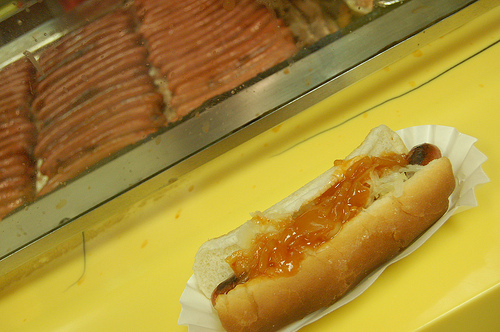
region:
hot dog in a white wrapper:
[181, 114, 483, 329]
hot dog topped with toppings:
[168, 122, 484, 329]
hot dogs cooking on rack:
[0, 4, 281, 171]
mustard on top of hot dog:
[243, 169, 383, 269]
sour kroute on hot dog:
[233, 163, 418, 275]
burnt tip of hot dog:
[397, 139, 446, 166]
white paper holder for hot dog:
[451, 120, 491, 205]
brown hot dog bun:
[365, 169, 446, 233]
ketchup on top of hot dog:
[205, 219, 322, 278]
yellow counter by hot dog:
[48, 234, 165, 319]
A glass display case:
[1, 0, 478, 253]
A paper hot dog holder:
[175, 123, 490, 330]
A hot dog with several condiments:
[191, 123, 456, 330]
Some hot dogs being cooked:
[0, 0, 293, 224]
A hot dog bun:
[191, 124, 456, 329]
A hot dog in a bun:
[212, 143, 446, 303]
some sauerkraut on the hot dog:
[228, 153, 425, 278]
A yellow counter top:
[1, 0, 498, 331]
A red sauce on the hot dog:
[226, 149, 406, 280]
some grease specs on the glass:
[3, 5, 316, 245]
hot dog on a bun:
[180, 119, 487, 328]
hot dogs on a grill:
[42, 93, 163, 122]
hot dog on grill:
[185, 39, 269, 57]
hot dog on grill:
[55, 40, 137, 50]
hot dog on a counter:
[165, 119, 484, 326]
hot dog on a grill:
[8, 139, 35, 191]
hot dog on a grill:
[10, 60, 28, 122]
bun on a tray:
[199, 122, 454, 322]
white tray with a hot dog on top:
[185, 126, 486, 328]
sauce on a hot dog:
[175, 155, 440, 327]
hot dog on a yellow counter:
[167, 115, 493, 329]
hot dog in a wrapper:
[437, 118, 486, 201]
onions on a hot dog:
[375, 168, 414, 193]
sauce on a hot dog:
[254, 233, 303, 267]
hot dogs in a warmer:
[152, 6, 253, 77]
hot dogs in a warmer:
[42, 45, 139, 129]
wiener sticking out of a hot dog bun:
[406, 140, 438, 163]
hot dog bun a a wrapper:
[235, 279, 327, 311]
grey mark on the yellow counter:
[60, 231, 104, 292]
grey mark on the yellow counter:
[295, 35, 499, 119]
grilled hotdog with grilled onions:
[160, 117, 451, 330]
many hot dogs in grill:
[1, 1, 338, 224]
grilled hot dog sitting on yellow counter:
[154, 99, 496, 330]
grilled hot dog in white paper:
[2, 0, 496, 327]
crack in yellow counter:
[284, 4, 497, 156]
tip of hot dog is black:
[148, 116, 498, 330]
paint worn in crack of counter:
[0, 163, 228, 301]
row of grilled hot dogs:
[22, 9, 180, 173]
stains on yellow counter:
[124, 203, 199, 246]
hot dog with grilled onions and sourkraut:
[163, 122, 490, 330]